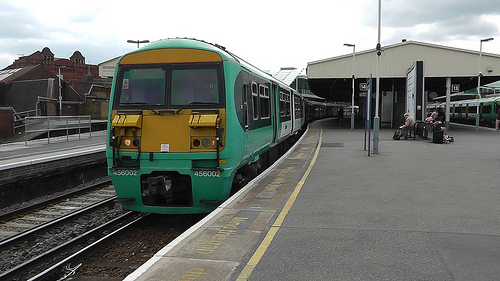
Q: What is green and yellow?
A: The train.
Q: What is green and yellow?
A: The train.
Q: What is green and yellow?
A: The train.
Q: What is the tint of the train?
A: Green and yellow.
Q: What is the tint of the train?
A: Green and yellow.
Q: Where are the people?
A: Sitting on the bench.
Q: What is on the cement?
A: Yellow letter.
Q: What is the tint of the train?
A: Aqua and yellow.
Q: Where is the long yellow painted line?
A: On the cement.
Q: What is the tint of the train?
A: Yellow and green.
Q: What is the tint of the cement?
A: Gray.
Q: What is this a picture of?
A: Front of the train.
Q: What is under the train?
A: Train tracks.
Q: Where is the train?
A: On the track.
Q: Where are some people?
A: Sitting on a bench at the platform.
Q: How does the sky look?
A: Cloudy.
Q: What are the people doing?
A: Waiting for their trains.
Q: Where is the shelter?
A: On the platform.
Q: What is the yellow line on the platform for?
A: Marks off a warning area.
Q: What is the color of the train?
A: Yellow and green.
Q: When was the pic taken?
A: During the day.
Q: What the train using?
A: Rail.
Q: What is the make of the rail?
A: Metal.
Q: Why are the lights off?
A: The sun is out.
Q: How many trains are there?
A: 1.